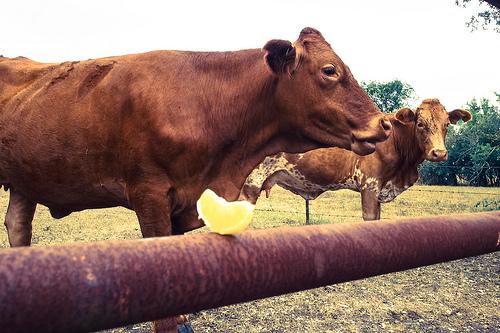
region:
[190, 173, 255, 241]
Orange slice on the pole.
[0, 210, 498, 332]
Pole in the forefront.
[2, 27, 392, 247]
Brown cow in the forefront.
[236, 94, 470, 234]
Brown and white cow in the back.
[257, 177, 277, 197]
Nipple on the cow.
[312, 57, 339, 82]
black eye on the cow.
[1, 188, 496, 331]
Grass covering the ground.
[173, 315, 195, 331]
Black hoof on the ground.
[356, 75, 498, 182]
Trees in the background.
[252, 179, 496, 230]
Barbed wire fence in the background.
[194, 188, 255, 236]
slice of orange sitting on railing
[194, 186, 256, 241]
a piece of tangerine a railing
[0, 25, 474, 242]
two brown cows standing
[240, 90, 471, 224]
a brown cow with spots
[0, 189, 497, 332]
a rusty railing with a tangerine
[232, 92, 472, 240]
a cow with an udder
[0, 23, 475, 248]
two cows in the field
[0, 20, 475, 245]
two brown cows in the field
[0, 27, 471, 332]
the cows are standing in dirt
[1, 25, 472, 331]
two brown cows are standing in dirt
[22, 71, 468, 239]
The cows are brown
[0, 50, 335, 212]
the cow is brown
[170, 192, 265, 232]
A lemon is on the fence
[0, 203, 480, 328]
The fence is made of metal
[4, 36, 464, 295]
The cows are fenced in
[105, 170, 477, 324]
Cows in a grassy field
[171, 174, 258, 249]
Lemon on a metal pole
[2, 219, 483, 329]
The pole is metal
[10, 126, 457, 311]
cows standing on grass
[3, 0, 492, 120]
The sky is clear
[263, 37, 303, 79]
ear of the cow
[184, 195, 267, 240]
lemon is on fence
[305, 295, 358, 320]
grass on the ground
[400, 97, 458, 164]
head of the cow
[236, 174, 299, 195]
udder of the cow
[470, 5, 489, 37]
leaves on the tree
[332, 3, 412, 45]
the sky is white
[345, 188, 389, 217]
leg of the cow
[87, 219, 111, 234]
grass under the cow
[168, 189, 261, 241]
slice of the lemon